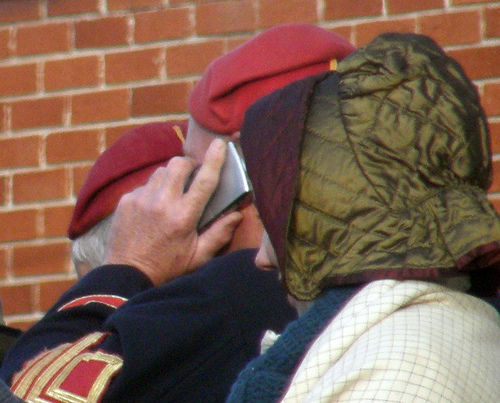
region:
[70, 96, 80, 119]
part of a brick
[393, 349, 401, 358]
part of a shoulder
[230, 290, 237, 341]
part of a pilloe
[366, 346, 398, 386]
edge of a win dow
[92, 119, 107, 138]
part of a building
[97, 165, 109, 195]
part of a brick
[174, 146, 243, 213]
person talking on a cell phone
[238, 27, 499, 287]
man wearing a green hood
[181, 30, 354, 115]
man wearing a red hat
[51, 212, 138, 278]
man with gray hair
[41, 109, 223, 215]
man wearing a red hat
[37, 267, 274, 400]
man wearing a blue jacket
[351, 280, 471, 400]
woman wearing a white jacket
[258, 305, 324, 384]
woman wearing a blue scarf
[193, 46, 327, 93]
man wearing a red hat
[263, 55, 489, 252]
woman wearing a green scarf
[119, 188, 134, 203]
the white finger of a hand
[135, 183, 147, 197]
the white finger of a hand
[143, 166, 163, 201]
the white finger of a hand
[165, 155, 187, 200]
the white finger of a hand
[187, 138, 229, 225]
the white finger of a hand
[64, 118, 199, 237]
the red cap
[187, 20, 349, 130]
the red cap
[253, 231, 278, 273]
the nose of a woman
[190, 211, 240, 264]
the thumb of a hand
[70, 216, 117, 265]
the grey hair on the head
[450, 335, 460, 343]
part of a shirt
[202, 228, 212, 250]
part of a trouser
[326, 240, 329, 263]
part of a jacket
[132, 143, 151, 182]
part of a wall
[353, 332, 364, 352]
part of a shoulder